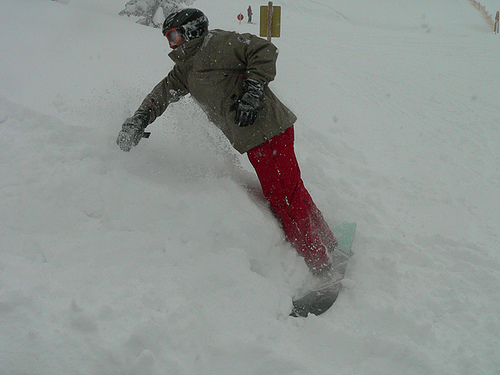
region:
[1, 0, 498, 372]
thick, fresh, powdery snow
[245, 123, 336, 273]
bright red ski pants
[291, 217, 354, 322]
snowboard covered in snow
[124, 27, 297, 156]
plain gray ski jacket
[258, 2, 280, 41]
back of sign in snow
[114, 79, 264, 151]
warm black gloves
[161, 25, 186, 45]
red rimmed ski goggles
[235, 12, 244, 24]
red sign in distance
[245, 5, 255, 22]
person skiing in distance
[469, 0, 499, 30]
orange ski fence boundary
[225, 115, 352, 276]
The snowboarder wears red pants.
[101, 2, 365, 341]
The snowboarder leans into the snow.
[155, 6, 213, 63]
The snowboarder wears a helmet.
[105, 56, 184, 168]
The snowboarder's right arm is extended.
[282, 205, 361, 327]
The snowboard is gray and green.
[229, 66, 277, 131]
The snowboarder wears gloves.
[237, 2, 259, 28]
A skier is in the background.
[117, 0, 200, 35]
A tree is visible.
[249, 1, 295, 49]
A sign is visible.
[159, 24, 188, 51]
The snowboarder wears red goggles.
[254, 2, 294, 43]
A yellow sign in the snow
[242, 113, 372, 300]
Red snow pants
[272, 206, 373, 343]
A snow board in the snow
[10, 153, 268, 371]
The snow is white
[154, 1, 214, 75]
This person is wearing a helmet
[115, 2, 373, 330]
Three people in the picture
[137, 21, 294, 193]
A heavy grey jacket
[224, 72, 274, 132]
A black glove with snow on it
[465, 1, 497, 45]
An orange fence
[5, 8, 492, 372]
People going down a hill in the snow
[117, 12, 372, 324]
Action figure in snow.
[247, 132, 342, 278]
Red pants on figure.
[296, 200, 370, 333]
Skateboard under figure's feet.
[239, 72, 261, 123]
Black glove on figure's hand.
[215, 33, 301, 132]
Left arm of figure bent.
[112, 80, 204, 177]
Right arm of figure extended.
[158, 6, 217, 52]
Black helmet on figure's head.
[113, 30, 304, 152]
Beige jacket on figure's torso.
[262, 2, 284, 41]
Small sign in snow.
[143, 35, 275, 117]
Bunched sleeves on figure's jacket.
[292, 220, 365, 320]
a snowboard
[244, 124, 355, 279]
red snow pants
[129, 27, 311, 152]
a gray winter ski jacket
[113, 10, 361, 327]
a person riding on a snowboard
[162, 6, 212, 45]
a black ski helmet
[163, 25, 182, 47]
ski goggles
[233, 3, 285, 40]
signs on the ski trail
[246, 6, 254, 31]
a person standing on the ski trail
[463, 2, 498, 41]
a fence lining the ski trail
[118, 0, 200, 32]
trees on the ski trail